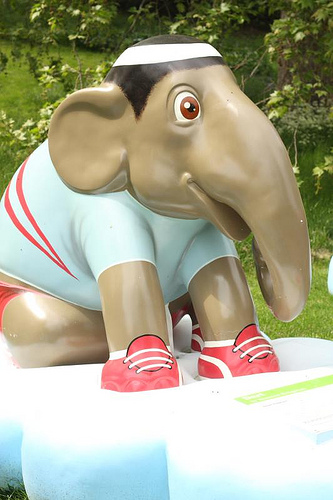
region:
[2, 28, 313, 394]
statue of elephant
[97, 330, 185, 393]
red sneakers on elephant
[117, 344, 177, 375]
white shoe laces on red sneakers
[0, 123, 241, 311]
blue short sleeve shirt on elephant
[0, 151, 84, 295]
red stripe pattern on blue shirt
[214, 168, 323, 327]
elephant trunk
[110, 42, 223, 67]
white head band on elephant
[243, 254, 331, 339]
green grass on ground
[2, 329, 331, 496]
blue platform for elephant statue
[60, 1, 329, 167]
green foliage bordering gass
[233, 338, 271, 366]
White laces on tennis shoe.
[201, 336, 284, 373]
Elephant is wearing red shoe.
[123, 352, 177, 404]
Elephant is wearing tennis shoe.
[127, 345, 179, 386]
White laces on elephant's shoe.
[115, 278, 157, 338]
Elephant has gray leg.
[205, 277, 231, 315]
Elephant has gray leg.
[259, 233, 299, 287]
Elephant has gray trunk.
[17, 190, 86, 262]
Elephant wearing white and red shirt.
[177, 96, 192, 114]
Elephant has brown eye.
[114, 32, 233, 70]
White band around elephant's head.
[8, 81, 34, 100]
this is the grass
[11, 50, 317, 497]
this is a statue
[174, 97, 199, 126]
that is the eye part of the statue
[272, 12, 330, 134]
these are leaves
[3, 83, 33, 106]
the grass is green in colour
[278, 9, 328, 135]
the leaves are green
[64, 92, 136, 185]
that is the ear of the statue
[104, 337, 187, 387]
those are the shoes of the statue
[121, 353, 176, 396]
the shoes are red in colour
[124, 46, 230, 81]
the head is black and white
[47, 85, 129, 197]
elephant statue's right ear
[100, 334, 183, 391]
elephant statue's red right shoe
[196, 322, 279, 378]
elephant statue's red left shoe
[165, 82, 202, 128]
right eye on elephant statue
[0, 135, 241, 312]
white shirt with red stripe on elephant statue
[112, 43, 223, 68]
white headband on elephant's head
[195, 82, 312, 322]
trunk on elephant statue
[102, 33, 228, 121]
black hair on elephant statue's head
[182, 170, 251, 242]
mouth on elephant statue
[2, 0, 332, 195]
green bushes in the background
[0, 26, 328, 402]
statue of an elephant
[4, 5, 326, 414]
elephant statue in a green field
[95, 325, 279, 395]
red shoes of elephant statue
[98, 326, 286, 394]
shoes has white pins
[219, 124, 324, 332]
trunk of elephant statue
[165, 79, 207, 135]
eye of elephant statue is brown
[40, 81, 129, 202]
ear of elephant statue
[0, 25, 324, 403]
elephant statue wears a blue shirt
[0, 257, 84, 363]
elephant statue has a red short